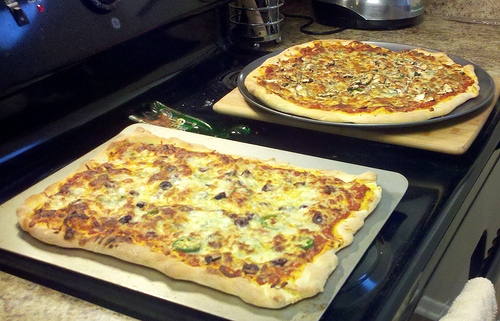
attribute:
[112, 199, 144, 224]
olives — black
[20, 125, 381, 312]
pizza — baked, rectangle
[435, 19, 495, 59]
counter — brown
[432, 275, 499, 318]
towel — white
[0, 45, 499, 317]
stove — black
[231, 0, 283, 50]
holder — silver, spatula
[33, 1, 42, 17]
circle — red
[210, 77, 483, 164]
board — wood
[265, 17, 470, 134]
pizza — sitting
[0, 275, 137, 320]
counter top — speckled, tan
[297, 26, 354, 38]
cord — black, appliance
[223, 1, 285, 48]
utensil holder — stainless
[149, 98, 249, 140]
spoon — green, plate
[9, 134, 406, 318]
baking sheet — thin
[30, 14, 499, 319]
stove. — black, top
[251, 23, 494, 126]
pizza — round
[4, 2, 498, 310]
appliance — stainless, black, bottom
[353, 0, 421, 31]
kettle — silver, bottom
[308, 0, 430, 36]
kettle — bottom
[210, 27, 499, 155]
cutting board — square, wooden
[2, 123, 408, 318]
dish — pizza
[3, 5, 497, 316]
stove — top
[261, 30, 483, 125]
pizza — round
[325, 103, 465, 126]
crust — brown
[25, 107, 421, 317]
sheet — cookie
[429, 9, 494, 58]
counter — kitchen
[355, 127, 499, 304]
stove — kitchen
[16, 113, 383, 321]
trays — pizza